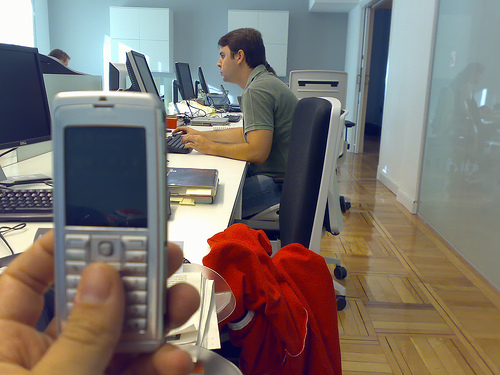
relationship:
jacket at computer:
[202, 223, 342, 375] [126, 47, 198, 150]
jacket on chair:
[199, 219, 345, 374] [275, 95, 349, 339]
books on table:
[156, 163, 246, 215] [64, 154, 334, 362]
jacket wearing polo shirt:
[202, 223, 342, 375] [241, 78, 296, 168]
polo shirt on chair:
[241, 64, 299, 177] [275, 87, 349, 304]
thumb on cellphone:
[27, 260, 124, 372] [49, 90, 168, 356]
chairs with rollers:
[216, 85, 375, 325] [313, 183, 359, 313]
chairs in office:
[216, 85, 375, 325] [1, 2, 498, 373]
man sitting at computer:
[168, 17, 304, 227] [123, 52, 201, 152]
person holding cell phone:
[1, 36, 198, 367] [39, 96, 246, 324]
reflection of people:
[433, 62, 498, 210] [45, 20, 329, 202]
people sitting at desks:
[45, 20, 329, 202] [3, 85, 253, 359]